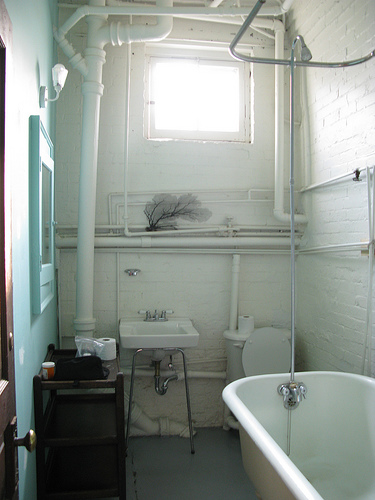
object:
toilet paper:
[96, 337, 117, 361]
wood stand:
[31, 342, 125, 498]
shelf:
[33, 346, 127, 499]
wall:
[13, 203, 24, 222]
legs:
[126, 348, 195, 455]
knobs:
[164, 310, 175, 319]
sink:
[117, 309, 200, 348]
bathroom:
[2, 0, 371, 495]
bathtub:
[222, 365, 374, 498]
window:
[146, 57, 243, 141]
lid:
[241, 326, 292, 376]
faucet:
[275, 381, 310, 412]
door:
[0, 35, 36, 496]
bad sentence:
[124, 452, 147, 467]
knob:
[14, 429, 38, 452]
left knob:
[137, 308, 151, 319]